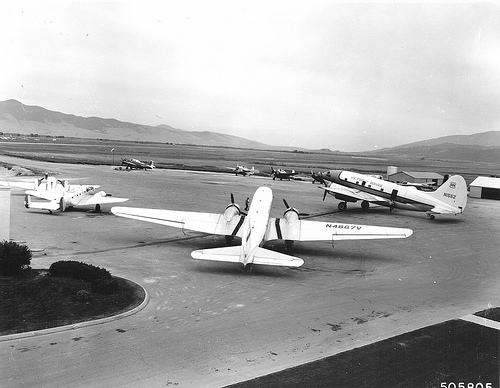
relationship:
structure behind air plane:
[376, 163, 445, 180] [306, 168, 468, 220]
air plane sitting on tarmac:
[110, 186, 415, 275] [327, 247, 474, 297]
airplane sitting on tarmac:
[225, 162, 259, 178] [5, 157, 498, 384]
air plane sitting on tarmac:
[306, 168, 468, 220] [5, 157, 498, 384]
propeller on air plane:
[223, 191, 242, 213] [110, 186, 415, 275]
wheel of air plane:
[335, 199, 352, 214] [309, 161, 472, 220]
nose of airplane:
[316, 169, 328, 184] [305, 165, 470, 219]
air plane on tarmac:
[306, 168, 468, 220] [5, 157, 498, 384]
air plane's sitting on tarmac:
[0, 172, 129, 215] [5, 157, 498, 384]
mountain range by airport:
[2, 97, 497, 163] [2, 140, 496, 387]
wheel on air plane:
[338, 202, 348, 211] [306, 168, 468, 220]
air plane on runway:
[306, 168, 468, 220] [1, 155, 498, 387]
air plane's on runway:
[0, 172, 129, 215] [1, 155, 498, 387]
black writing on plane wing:
[322, 216, 364, 231] [274, 205, 411, 240]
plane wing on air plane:
[274, 205, 411, 240] [110, 186, 415, 275]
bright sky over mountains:
[3, 0, 497, 126] [5, 93, 499, 153]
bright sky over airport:
[3, 0, 497, 126] [2, 140, 496, 387]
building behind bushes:
[0, 168, 17, 239] [46, 257, 109, 279]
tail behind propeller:
[187, 244, 306, 281] [281, 195, 309, 215]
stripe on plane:
[338, 177, 403, 207] [311, 155, 472, 226]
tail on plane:
[425, 170, 475, 212] [311, 155, 472, 226]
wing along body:
[110, 205, 245, 239] [228, 197, 278, 244]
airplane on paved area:
[114, 157, 155, 173] [2, 169, 498, 386]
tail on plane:
[191, 246, 305, 268] [106, 185, 413, 270]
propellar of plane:
[276, 194, 305, 219] [99, 174, 421, 284]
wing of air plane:
[308, 214, 418, 254] [140, 182, 385, 287]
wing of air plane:
[107, 201, 224, 237] [109, 181, 415, 272]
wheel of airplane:
[362, 198, 370, 209] [305, 165, 470, 219]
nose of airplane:
[316, 170, 328, 179] [109, 182, 414, 277]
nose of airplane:
[271, 166, 278, 178] [305, 165, 470, 219]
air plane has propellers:
[110, 186, 415, 275] [203, 182, 318, 224]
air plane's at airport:
[0, 172, 129, 215] [2, 140, 496, 387]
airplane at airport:
[114, 157, 155, 173] [2, 140, 496, 387]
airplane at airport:
[225, 162, 259, 178] [2, 140, 496, 387]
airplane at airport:
[263, 167, 299, 182] [2, 140, 496, 387]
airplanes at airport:
[309, 170, 324, 184] [2, 140, 496, 387]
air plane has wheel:
[306, 168, 468, 220] [333, 200, 348, 212]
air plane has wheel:
[306, 168, 468, 220] [357, 200, 369, 210]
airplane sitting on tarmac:
[263, 167, 299, 182] [75, 162, 302, 186]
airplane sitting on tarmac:
[225, 162, 259, 178] [75, 162, 302, 186]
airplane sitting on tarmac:
[114, 157, 155, 173] [75, 162, 302, 186]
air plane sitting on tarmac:
[306, 168, 468, 220] [14, 167, 454, 386]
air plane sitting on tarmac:
[110, 186, 415, 275] [14, 167, 454, 386]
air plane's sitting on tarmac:
[0, 172, 129, 215] [14, 167, 454, 386]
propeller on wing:
[223, 192, 247, 216] [278, 207, 416, 246]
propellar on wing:
[282, 197, 310, 220] [103, 189, 249, 238]